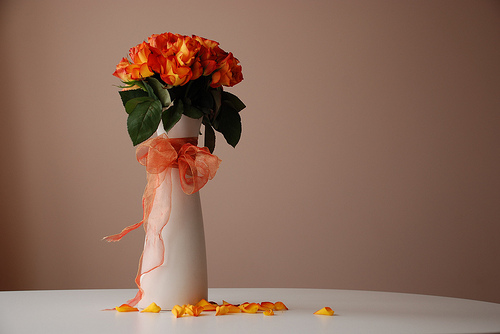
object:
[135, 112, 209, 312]
vase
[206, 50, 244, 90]
flower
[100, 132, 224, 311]
ribbon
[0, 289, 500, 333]
table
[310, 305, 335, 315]
petal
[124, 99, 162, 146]
leaf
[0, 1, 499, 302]
wall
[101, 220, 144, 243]
wire